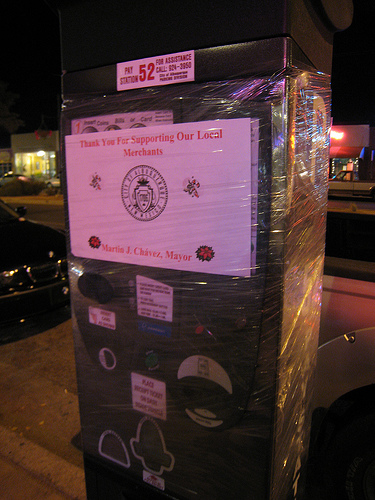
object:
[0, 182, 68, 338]
car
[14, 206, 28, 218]
side mirror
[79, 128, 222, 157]
writing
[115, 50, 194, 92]
writing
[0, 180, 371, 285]
road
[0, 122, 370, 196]
building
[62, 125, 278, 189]
wall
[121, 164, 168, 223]
picture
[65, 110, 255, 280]
sign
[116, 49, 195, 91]
letter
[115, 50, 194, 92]
sign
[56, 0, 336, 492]
package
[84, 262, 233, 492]
stickers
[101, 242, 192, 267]
mayor's name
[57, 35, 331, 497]
wrapping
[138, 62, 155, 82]
printed number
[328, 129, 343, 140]
light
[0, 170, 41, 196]
car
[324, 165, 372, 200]
car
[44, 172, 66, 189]
car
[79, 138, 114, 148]
thank you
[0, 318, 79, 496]
concrete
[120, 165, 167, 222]
symbol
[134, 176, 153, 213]
city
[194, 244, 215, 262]
drawing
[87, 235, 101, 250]
drawing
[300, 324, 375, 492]
car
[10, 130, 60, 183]
store front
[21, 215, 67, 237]
line